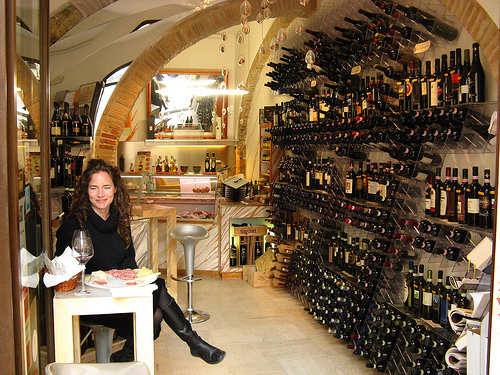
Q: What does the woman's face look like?
A: Happy.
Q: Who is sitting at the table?
A: The woman.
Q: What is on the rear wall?
A: A mirror.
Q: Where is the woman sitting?
A: At the table.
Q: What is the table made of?
A: Wood.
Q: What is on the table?
A: Wine glasses.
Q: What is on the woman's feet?
A: Black boots.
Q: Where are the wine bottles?
A: On the right wall.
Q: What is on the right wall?
A: Wine bottles.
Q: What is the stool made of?
A: Metal.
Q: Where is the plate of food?
A: White table.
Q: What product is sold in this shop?
A: Wine.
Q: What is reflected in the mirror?
A: Light.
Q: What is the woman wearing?
A: Black clothes.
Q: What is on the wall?
A: Wine bottles.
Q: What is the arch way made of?
A: Brick.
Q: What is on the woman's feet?
A: Boots.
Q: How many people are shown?
A: One.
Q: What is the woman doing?
A: Sitting.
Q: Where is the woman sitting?
A: Table.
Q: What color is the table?
A: White.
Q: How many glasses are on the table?
A: Two.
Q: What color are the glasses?
A: Clear.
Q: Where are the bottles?
A: Shelves.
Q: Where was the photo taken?
A: Wine room.